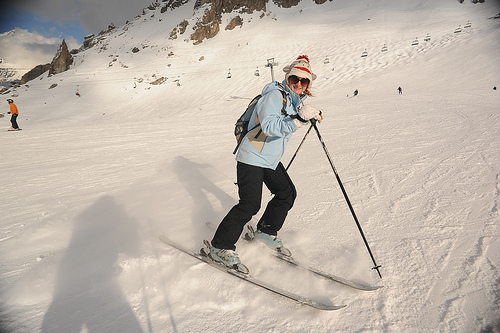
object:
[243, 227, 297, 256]
foot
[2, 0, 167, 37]
grey cloud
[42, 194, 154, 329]
shadows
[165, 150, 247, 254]
shadows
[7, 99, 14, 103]
cap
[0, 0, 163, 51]
sky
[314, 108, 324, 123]
hand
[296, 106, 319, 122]
hand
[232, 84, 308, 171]
jacket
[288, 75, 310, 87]
glasses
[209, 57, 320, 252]
man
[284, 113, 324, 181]
ski pole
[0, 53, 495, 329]
ground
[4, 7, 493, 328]
mountain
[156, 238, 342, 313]
skis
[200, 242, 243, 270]
feet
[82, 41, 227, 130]
hillside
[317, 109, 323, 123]
gloves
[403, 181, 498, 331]
tracks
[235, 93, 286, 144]
pack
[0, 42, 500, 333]
snow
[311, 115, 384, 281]
ski pole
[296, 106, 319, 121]
gloves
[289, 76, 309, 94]
woman's face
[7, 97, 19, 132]
man